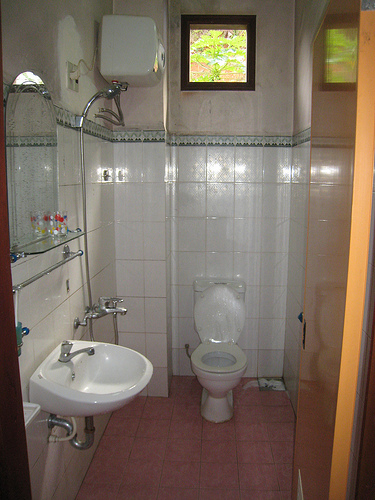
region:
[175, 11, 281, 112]
A brown framed window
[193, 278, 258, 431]
White toilet seat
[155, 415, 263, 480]
Red square toilet tiles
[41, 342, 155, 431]
A white sink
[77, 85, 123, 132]
A silver shower head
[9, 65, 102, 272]
A mirror with stains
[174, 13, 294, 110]
Tree leaves outside the bathroom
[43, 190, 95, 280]
A cup with colorful dots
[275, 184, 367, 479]
A brown bathroom door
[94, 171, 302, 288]
White square bathroom tiles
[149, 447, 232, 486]
tiles on the floor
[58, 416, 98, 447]
a metal pipe under the sink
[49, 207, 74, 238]
a glass with a polka dot design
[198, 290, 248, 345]
a toilet seat lid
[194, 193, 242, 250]
white tile on the wall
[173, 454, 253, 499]
lines between the tiles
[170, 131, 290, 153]
patterned wall paper on the wall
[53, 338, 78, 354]
a knob on the faucet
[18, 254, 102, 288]
a metal towel rack mounted on the wall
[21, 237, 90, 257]
a clear glass shelf over the sink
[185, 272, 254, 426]
White toilet in bathroom.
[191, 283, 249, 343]
Lid up on toilet.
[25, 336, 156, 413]
White bathroom sink mounted on white tile wall.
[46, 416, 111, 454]
Drain pipe for sink.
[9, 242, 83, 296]
Towel bar above bathroom sink.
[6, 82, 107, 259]
Mirror with shelf mounted above towel bar.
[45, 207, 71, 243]
Multi colored glass sitting on mirror shelf.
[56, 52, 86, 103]
Electrical outlet in bathroom.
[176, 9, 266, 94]
Window mounted high up on bathroom wall.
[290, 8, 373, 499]
Open door to bathroom.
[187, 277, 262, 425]
white toilet against the wall of bathroom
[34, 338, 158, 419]
white sink with chrome faucet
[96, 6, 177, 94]
white water tank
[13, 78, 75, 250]
mirror on the wall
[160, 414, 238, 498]
red tile on bathroom floor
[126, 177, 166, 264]
white tile on wall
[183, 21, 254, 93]
stained glass window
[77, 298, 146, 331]
faucet made of chrome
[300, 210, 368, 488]
yellow door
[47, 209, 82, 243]
glass with red design on shelf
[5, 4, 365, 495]
photograph of a restroom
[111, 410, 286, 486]
floor of restroom is covered in pink tiles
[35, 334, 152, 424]
sink is white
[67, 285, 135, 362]
large faucet affixed to wall beside sink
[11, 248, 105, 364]
metal towel rack above sink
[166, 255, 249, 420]
white toilet next to wall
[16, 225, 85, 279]
shelf above towel rack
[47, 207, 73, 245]
colorful cup on shelf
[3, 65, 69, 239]
mirror with a curved top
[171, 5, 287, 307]
small window situated high up on wall